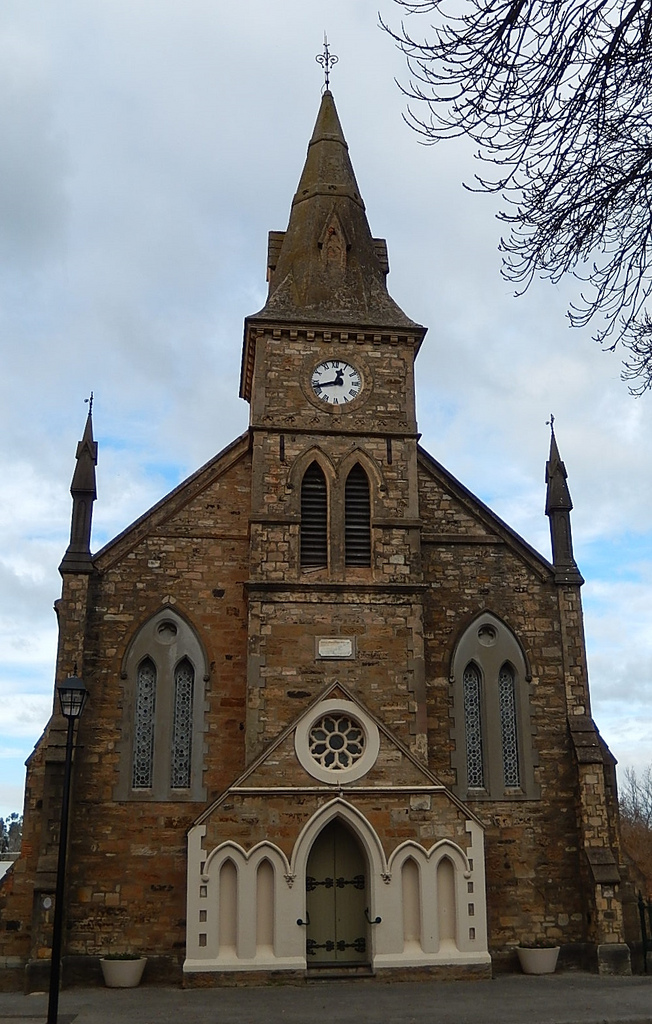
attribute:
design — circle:
[285, 691, 382, 788]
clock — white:
[298, 343, 418, 423]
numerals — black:
[310, 363, 337, 397]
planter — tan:
[74, 926, 180, 985]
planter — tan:
[507, 914, 568, 970]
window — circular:
[272, 707, 369, 778]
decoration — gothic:
[303, 707, 377, 769]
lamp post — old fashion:
[55, 657, 102, 986]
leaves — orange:
[601, 771, 650, 942]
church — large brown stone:
[107, 193, 601, 958]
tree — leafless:
[412, 40, 640, 287]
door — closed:
[270, 793, 400, 995]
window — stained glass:
[444, 621, 545, 823]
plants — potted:
[502, 926, 556, 986]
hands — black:
[315, 367, 350, 389]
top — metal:
[308, 29, 344, 89]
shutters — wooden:
[299, 445, 379, 581]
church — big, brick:
[7, 32, 624, 981]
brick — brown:
[262, 541, 289, 551]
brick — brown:
[156, 542, 198, 570]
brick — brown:
[177, 540, 236, 622]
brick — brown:
[135, 550, 220, 591]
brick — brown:
[84, 725, 116, 786]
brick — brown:
[94, 810, 167, 879]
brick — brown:
[108, 844, 182, 918]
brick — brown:
[439, 552, 498, 605]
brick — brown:
[446, 566, 528, 609]